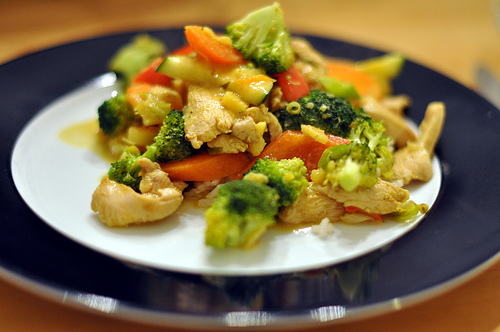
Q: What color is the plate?
A: White.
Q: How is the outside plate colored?
A: Blue.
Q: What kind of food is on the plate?
A: Chicken, broccoli, tomatoes, and cucumbers.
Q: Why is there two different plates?
A: So the food doesn't spill on the table.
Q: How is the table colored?
A: Tan.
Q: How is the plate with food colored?
A: White.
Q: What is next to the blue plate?
A: A knife.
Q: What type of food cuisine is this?
A: Asian cuisine.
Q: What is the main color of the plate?
A: White.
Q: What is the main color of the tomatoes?
A: Red.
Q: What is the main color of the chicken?
A: Brown.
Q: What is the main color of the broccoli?
A: Green.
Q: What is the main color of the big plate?
A: Grey.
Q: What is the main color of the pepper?
A: Yellow.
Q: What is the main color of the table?
A: Brown.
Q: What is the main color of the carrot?
A: Orange.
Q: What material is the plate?
A: Ceramic.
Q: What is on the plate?
A: Food.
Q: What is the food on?
A: A white plate with blue trim.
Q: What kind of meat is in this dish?
A: Chicken.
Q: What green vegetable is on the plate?
A: Broccoli.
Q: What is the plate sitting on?
A: The table.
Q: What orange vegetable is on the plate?
A: Carrots.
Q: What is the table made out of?
A: Wood.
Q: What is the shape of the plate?
A: Round.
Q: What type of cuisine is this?
A: Stir Fry.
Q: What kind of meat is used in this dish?
A: Chicken.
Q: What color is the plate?
A: Blue.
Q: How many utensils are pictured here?
A: One.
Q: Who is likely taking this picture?
A: The diner.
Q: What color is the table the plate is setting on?
A: Brown.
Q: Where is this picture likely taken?
A: A restaurant.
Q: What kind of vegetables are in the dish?
A: Carrots and broccoli.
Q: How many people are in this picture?
A: Zero.